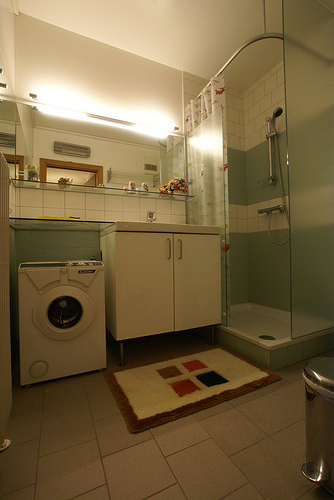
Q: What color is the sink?
A: White.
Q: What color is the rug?
A: Cream.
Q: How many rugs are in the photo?
A: One.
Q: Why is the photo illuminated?
A: Light fixtures.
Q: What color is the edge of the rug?
A: Brown.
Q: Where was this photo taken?
A: In a bathroom.